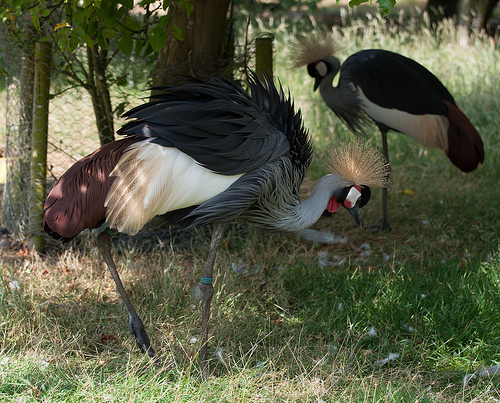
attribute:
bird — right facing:
[41, 59, 394, 376]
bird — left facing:
[294, 32, 489, 235]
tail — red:
[40, 131, 153, 241]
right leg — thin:
[192, 208, 225, 382]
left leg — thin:
[90, 214, 165, 367]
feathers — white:
[96, 137, 245, 240]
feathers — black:
[117, 74, 313, 175]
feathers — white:
[176, 199, 497, 396]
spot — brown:
[23, 246, 160, 304]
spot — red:
[89, 324, 124, 350]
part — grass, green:
[269, 265, 498, 385]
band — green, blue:
[197, 272, 218, 287]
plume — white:
[324, 140, 393, 191]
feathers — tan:
[419, 114, 448, 152]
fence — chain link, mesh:
[0, 13, 277, 248]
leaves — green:
[12, 1, 193, 65]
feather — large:
[112, 151, 181, 233]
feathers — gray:
[259, 151, 344, 243]